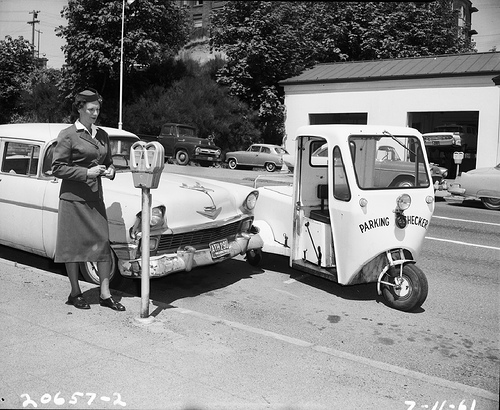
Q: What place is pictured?
A: It is a street.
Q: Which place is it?
A: It is a street.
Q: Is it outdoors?
A: Yes, it is outdoors.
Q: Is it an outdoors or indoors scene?
A: It is outdoors.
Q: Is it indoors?
A: No, it is outdoors.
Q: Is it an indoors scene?
A: No, it is outdoors.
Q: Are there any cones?
A: No, there are no cones.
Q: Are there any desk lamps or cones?
A: No, there are no cones or desk lamps.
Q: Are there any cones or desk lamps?
A: No, there are no cones or desk lamps.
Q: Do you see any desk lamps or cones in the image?
A: No, there are no cones or desk lamps.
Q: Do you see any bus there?
A: No, there are no buses.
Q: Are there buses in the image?
A: No, there are no buses.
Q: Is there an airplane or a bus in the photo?
A: No, there are no buses or airplanes.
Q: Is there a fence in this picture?
A: No, there are no fences.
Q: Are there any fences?
A: No, there are no fences.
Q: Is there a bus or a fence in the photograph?
A: No, there are no fences or buses.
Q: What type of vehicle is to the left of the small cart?
A: The vehicle is a car.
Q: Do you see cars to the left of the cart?
A: Yes, there is a car to the left of the cart.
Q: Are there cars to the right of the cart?
A: No, the car is to the left of the cart.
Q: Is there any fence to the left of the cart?
A: No, there is a car to the left of the cart.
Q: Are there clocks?
A: No, there are no clocks.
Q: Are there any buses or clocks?
A: No, there are no clocks or buses.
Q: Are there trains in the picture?
A: No, there are no trains.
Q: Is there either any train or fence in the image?
A: No, there are no trains or fences.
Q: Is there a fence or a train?
A: No, there are no trains or fences.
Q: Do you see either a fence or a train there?
A: No, there are no trains or fences.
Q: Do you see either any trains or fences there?
A: No, there are no trains or fences.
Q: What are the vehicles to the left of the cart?
A: The vehicles are cars.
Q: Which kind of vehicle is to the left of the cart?
A: The vehicles are cars.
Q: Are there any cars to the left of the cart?
A: Yes, there are cars to the left of the cart.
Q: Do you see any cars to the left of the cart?
A: Yes, there are cars to the left of the cart.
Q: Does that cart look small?
A: Yes, the cart is small.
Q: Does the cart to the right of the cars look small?
A: Yes, the cart is small.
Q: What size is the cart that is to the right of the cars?
A: The cart is small.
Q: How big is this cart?
A: The cart is small.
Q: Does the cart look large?
A: No, the cart is small.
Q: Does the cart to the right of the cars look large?
A: No, the cart is small.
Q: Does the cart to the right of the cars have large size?
A: No, the cart is small.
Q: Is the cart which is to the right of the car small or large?
A: The cart is small.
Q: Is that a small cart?
A: Yes, that is a small cart.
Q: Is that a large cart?
A: No, that is a small cart.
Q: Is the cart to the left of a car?
A: No, the cart is to the right of a car.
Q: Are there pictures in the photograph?
A: No, there are no pictures.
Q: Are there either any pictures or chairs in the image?
A: No, there are no pictures or chairs.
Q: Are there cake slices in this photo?
A: No, there are no cake slices.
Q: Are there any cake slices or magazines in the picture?
A: No, there are no cake slices or magazines.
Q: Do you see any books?
A: No, there are no books.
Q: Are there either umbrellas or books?
A: No, there are no books or umbrellas.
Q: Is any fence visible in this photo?
A: No, there are no fences.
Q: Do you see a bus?
A: No, there are no buses.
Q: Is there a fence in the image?
A: No, there are no fences.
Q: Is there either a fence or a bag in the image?
A: No, there are no fences or bags.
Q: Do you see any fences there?
A: No, there are no fences.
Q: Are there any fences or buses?
A: No, there are no fences or buses.